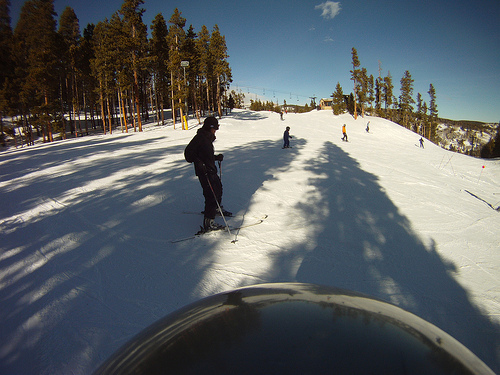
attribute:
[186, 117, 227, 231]
person — that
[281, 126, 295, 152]
person — that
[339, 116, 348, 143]
person — that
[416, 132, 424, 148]
person — that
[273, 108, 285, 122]
person — that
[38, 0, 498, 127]
sky — bright, Blue, vibrant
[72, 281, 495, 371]
snowmobile — round front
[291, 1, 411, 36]
clouds — small, wispy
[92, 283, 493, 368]
helmet — of photographer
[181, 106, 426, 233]
people — several, skiing , in the distance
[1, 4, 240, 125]
trees — group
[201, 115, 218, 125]
hat — Black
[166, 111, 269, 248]
skier — standing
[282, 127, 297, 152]
kid — small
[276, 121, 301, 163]
person — that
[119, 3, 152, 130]
tree — that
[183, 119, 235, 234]
person — that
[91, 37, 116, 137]
tree — that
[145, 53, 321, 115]
ski lift — in distance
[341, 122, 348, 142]
person — that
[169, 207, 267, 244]
skis — pair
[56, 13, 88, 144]
tree — that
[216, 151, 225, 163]
glove — black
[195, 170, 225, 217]
pants — black 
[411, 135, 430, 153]
person — that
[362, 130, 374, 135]
skis — snow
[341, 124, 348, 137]
sweater — orange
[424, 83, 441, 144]
tree — sparse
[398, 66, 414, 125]
tree — sparse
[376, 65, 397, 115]
tree — sparse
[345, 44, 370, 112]
tree — sparse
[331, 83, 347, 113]
tree — sparse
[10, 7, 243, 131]
tree — tall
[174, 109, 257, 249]
clothing — warm